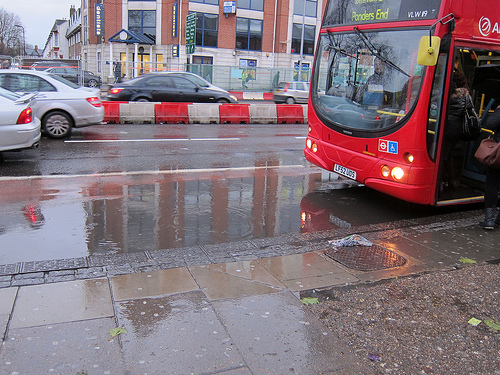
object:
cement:
[94, 163, 308, 254]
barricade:
[100, 101, 309, 125]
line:
[0, 165, 304, 181]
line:
[64, 137, 240, 142]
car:
[0, 86, 41, 152]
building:
[40, 0, 326, 92]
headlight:
[381, 165, 389, 177]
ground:
[0, 123, 499, 374]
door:
[435, 40, 500, 207]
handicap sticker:
[388, 141, 398, 154]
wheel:
[41, 112, 72, 140]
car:
[105, 72, 240, 104]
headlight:
[391, 167, 404, 179]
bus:
[304, 0, 500, 206]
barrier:
[229, 89, 273, 101]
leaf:
[108, 326, 128, 342]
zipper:
[26, 93, 40, 105]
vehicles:
[273, 81, 310, 105]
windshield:
[311, 26, 433, 132]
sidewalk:
[0, 207, 500, 375]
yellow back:
[422, 38, 433, 63]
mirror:
[417, 35, 442, 66]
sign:
[378, 139, 388, 153]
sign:
[351, 8, 390, 21]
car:
[0, 69, 105, 138]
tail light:
[16, 107, 32, 124]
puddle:
[0, 168, 434, 265]